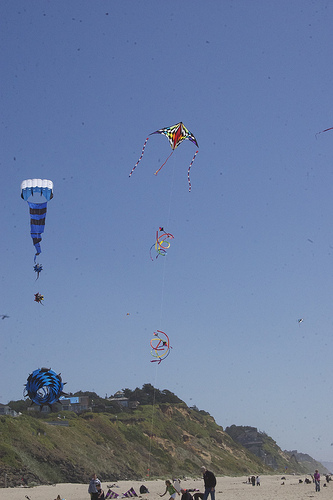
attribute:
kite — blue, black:
[27, 364, 58, 407]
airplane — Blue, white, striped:
[296, 318, 309, 327]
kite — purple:
[123, 487, 137, 496]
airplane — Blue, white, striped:
[116, 101, 226, 195]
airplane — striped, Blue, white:
[296, 315, 304, 325]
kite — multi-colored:
[127, 112, 202, 191]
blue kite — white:
[15, 168, 55, 292]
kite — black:
[118, 103, 205, 194]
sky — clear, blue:
[86, 188, 307, 306]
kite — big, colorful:
[147, 224, 176, 260]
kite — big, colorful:
[19, 176, 52, 306]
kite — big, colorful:
[127, 120, 200, 192]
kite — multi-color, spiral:
[148, 225, 174, 262]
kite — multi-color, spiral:
[149, 329, 170, 364]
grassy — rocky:
[115, 420, 170, 457]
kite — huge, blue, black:
[22, 359, 72, 416]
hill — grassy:
[1, 381, 327, 479]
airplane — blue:
[19, 170, 51, 262]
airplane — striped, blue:
[23, 175, 52, 280]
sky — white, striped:
[3, 4, 332, 461]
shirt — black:
[202, 471, 214, 492]